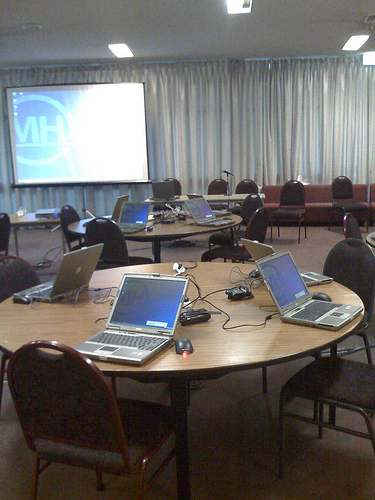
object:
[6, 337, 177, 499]
chair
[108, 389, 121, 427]
metal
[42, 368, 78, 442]
padding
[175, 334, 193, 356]
mouse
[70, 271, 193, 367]
computer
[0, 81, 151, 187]
screen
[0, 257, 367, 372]
table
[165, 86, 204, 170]
curtain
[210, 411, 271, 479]
floor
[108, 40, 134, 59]
lights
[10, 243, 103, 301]
laptops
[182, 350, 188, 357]
light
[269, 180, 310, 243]
chairs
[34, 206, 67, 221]
microphone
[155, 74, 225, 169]
wall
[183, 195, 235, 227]
computers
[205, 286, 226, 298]
wires